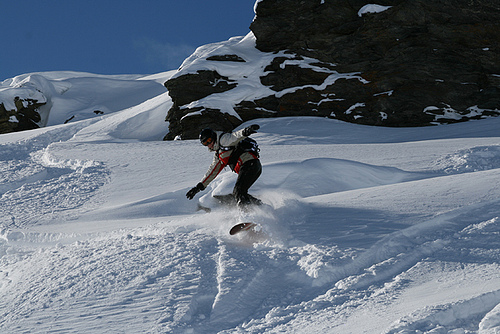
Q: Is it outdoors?
A: Yes, it is outdoors.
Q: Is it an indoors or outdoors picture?
A: It is outdoors.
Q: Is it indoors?
A: No, it is outdoors.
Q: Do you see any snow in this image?
A: Yes, there is snow.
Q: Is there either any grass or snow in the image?
A: Yes, there is snow.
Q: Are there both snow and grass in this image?
A: No, there is snow but no grass.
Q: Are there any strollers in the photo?
A: No, there are no strollers.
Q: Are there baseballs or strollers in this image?
A: No, there are no strollers or baseballs.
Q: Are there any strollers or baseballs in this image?
A: No, there are no strollers or baseballs.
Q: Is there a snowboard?
A: Yes, there is a snowboard.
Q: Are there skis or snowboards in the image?
A: Yes, there is a snowboard.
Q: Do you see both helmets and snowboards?
A: Yes, there are both a snowboard and a helmet.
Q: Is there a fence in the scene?
A: No, there are no fences.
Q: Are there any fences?
A: No, there are no fences.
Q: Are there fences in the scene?
A: No, there are no fences.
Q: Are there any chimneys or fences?
A: No, there are no fences or chimneys.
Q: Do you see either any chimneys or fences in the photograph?
A: No, there are no fences or chimneys.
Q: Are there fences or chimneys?
A: No, there are no fences or chimneys.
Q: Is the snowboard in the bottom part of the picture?
A: Yes, the snowboard is in the bottom of the image.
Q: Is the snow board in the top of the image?
A: No, the snow board is in the bottom of the image.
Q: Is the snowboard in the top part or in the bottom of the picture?
A: The snowboard is in the bottom of the image.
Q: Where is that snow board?
A: The snow board is in the snow.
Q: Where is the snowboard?
A: The snow board is in the snow.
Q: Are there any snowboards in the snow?
A: Yes, there is a snowboard in the snow.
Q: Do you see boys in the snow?
A: No, there is a snowboard in the snow.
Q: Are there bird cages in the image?
A: No, there are no bird cages.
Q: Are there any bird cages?
A: No, there are no bird cages.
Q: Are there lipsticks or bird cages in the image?
A: No, there are no bird cages or lipsticks.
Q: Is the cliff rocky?
A: Yes, the cliff is rocky.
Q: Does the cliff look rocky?
A: Yes, the cliff is rocky.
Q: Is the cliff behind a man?
A: Yes, the cliff is behind a man.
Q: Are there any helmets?
A: Yes, there is a helmet.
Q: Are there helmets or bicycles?
A: Yes, there is a helmet.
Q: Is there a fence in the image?
A: No, there are no fences.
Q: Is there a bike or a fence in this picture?
A: No, there are no fences or bikes.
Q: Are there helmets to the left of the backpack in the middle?
A: Yes, there is a helmet to the left of the backpack.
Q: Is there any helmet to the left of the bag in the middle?
A: Yes, there is a helmet to the left of the backpack.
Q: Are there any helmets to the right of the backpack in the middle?
A: No, the helmet is to the left of the backpack.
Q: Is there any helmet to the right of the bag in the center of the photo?
A: No, the helmet is to the left of the backpack.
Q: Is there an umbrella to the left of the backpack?
A: No, there is a helmet to the left of the backpack.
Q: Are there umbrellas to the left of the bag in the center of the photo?
A: No, there is a helmet to the left of the backpack.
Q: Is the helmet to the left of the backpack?
A: Yes, the helmet is to the left of the backpack.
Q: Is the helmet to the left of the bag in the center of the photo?
A: Yes, the helmet is to the left of the backpack.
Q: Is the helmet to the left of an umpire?
A: No, the helmet is to the left of the backpack.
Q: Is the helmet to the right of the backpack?
A: No, the helmet is to the left of the backpack.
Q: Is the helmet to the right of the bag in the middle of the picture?
A: No, the helmet is to the left of the backpack.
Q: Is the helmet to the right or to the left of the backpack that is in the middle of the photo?
A: The helmet is to the left of the backpack.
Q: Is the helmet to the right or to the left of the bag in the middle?
A: The helmet is to the left of the backpack.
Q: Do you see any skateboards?
A: No, there are no skateboards.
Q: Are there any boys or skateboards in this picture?
A: No, there are no skateboards or boys.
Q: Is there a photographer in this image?
A: No, there are no photographers.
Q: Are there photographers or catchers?
A: No, there are no photographers or catchers.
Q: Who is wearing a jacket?
A: The man is wearing a jacket.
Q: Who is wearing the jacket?
A: The man is wearing a jacket.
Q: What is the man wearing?
A: The man is wearing a jacket.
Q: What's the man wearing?
A: The man is wearing a jacket.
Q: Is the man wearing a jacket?
A: Yes, the man is wearing a jacket.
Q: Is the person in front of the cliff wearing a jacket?
A: Yes, the man is wearing a jacket.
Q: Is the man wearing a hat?
A: No, the man is wearing a jacket.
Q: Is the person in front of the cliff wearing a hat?
A: No, the man is wearing a jacket.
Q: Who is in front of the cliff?
A: The man is in front of the cliff.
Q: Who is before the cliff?
A: The man is in front of the cliff.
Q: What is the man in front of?
A: The man is in front of the cliff.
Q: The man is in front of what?
A: The man is in front of the cliff.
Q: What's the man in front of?
A: The man is in front of the cliff.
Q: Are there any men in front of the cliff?
A: Yes, there is a man in front of the cliff.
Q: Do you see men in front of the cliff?
A: Yes, there is a man in front of the cliff.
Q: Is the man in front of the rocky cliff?
A: Yes, the man is in front of the cliff.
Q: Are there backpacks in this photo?
A: Yes, there is a backpack.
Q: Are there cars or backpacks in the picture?
A: Yes, there is a backpack.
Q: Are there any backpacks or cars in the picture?
A: Yes, there is a backpack.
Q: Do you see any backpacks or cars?
A: Yes, there is a backpack.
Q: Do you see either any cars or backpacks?
A: Yes, there is a backpack.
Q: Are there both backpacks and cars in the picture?
A: No, there is a backpack but no cars.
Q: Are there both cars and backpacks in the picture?
A: No, there is a backpack but no cars.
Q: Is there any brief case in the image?
A: No, there are no briefcases.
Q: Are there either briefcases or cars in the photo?
A: No, there are no briefcases or cars.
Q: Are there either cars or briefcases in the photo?
A: No, there are no briefcases or cars.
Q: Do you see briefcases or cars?
A: No, there are no briefcases or cars.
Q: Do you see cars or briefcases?
A: No, there are no briefcases or cars.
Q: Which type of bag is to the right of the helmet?
A: The bag is a backpack.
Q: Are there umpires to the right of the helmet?
A: No, there is a backpack to the right of the helmet.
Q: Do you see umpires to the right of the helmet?
A: No, there is a backpack to the right of the helmet.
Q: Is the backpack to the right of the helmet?
A: Yes, the backpack is to the right of the helmet.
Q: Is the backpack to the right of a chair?
A: No, the backpack is to the right of the helmet.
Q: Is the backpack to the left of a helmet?
A: No, the backpack is to the right of a helmet.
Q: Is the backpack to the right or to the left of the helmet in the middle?
A: The backpack is to the right of the helmet.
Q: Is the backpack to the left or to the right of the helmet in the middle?
A: The backpack is to the right of the helmet.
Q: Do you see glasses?
A: No, there are no glasses.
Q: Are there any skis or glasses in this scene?
A: No, there are no glasses or skis.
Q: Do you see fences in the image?
A: No, there are no fences.